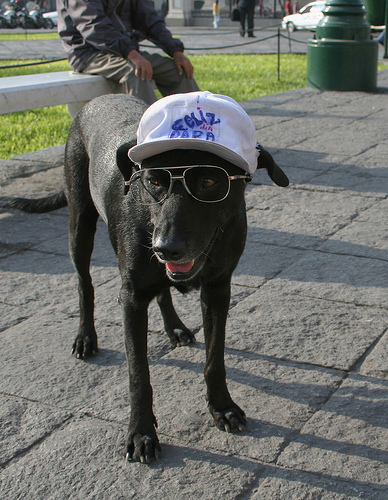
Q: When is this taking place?
A: Daytime.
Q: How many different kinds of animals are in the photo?
A: One.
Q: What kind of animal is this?
A: Dog.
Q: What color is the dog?
A: Black.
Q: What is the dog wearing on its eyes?
A: Glasses.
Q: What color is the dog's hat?
A: White, blue and red.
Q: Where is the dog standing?
A: Sidewalk.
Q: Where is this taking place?
A: On the sidewalk.